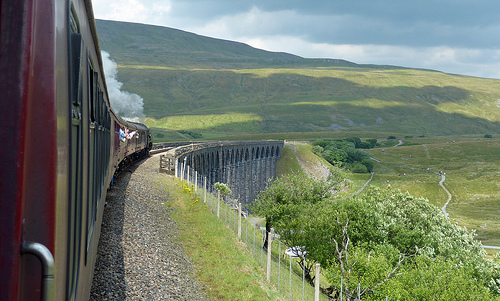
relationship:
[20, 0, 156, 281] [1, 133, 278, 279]
train on track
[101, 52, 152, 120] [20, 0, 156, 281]
smoke from train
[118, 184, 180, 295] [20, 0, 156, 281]
rocks by train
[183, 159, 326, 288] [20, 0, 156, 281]
fence by train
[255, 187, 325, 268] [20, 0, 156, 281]
tree below train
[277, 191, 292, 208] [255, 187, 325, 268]
leaves on tree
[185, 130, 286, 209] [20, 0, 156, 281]
bridge for train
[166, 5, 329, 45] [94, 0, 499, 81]
clouds in sky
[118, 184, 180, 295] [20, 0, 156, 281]
rocks next to train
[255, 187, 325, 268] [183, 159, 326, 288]
tree behind fence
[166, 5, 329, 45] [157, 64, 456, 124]
clouds make shadows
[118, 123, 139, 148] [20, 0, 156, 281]
person out of train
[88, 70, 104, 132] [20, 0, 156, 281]
window of train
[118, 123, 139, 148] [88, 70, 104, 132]
person hanging out window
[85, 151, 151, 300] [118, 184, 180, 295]
shadow on rocks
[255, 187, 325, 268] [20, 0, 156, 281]
tree by train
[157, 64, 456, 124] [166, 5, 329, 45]
shadows from clouds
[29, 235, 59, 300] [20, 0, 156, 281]
pole on train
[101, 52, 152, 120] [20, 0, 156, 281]
smoke above train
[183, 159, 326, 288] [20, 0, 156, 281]
fence next to train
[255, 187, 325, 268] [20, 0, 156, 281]
tree next to train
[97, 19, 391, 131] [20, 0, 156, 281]
hill beside train